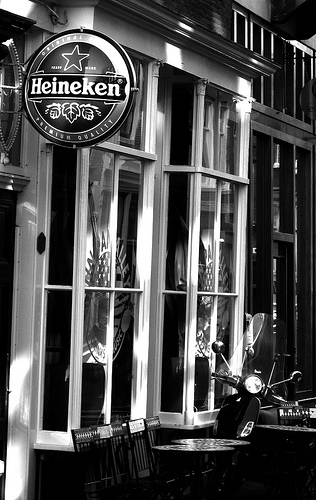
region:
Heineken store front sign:
[17, 34, 177, 203]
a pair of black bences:
[62, 394, 173, 483]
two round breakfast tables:
[155, 417, 276, 481]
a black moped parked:
[218, 334, 311, 451]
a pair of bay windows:
[49, 164, 261, 390]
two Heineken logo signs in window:
[72, 222, 255, 354]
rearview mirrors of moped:
[209, 342, 227, 356]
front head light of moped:
[240, 368, 266, 396]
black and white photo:
[6, 17, 304, 483]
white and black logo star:
[62, 40, 97, 71]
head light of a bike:
[254, 372, 262, 388]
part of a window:
[94, 384, 102, 394]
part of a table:
[190, 445, 198, 449]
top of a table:
[208, 441, 212, 446]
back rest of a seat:
[101, 444, 116, 449]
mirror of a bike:
[218, 345, 221, 349]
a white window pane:
[76, 329, 89, 357]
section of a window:
[175, 328, 182, 340]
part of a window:
[59, 323, 64, 335]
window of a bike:
[253, 328, 276, 361]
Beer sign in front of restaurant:
[5, 20, 138, 160]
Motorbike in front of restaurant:
[197, 326, 297, 436]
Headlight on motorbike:
[234, 364, 263, 396]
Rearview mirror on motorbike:
[199, 333, 234, 366]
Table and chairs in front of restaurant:
[57, 407, 247, 494]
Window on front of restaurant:
[169, 69, 237, 417]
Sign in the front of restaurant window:
[74, 192, 141, 370]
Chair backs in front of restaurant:
[61, 408, 163, 451]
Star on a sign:
[55, 45, 95, 71]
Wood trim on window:
[190, 162, 250, 189]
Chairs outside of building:
[72, 415, 183, 498]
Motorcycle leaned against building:
[210, 313, 300, 458]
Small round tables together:
[153, 437, 250, 498]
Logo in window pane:
[81, 229, 142, 366]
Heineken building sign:
[26, 27, 138, 149]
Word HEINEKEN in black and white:
[28, 73, 126, 101]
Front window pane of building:
[154, 79, 235, 423]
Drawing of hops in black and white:
[44, 101, 101, 123]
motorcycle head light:
[243, 373, 263, 394]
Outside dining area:
[68, 406, 314, 497]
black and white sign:
[32, 30, 135, 138]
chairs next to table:
[81, 417, 173, 495]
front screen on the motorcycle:
[237, 308, 296, 365]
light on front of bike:
[236, 361, 270, 397]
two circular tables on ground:
[167, 430, 231, 480]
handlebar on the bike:
[199, 340, 240, 394]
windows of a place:
[62, 248, 159, 345]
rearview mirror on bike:
[282, 363, 306, 391]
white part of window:
[69, 187, 95, 245]